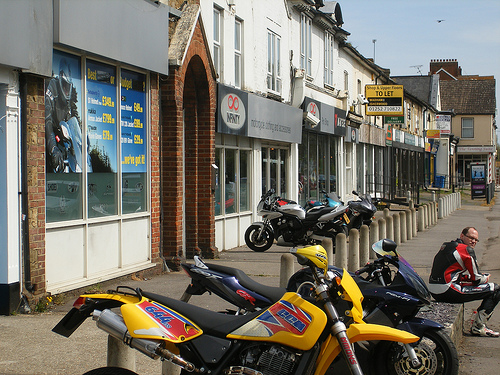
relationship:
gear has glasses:
[428, 227, 500, 338] [464, 233, 481, 244]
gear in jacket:
[428, 227, 500, 338] [426, 240, 489, 293]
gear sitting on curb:
[428, 227, 500, 338] [437, 303, 471, 357]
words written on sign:
[372, 87, 395, 102] [360, 85, 415, 123]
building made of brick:
[0, 0, 500, 316] [148, 0, 220, 261]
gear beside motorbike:
[428, 227, 500, 338] [183, 244, 463, 374]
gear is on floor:
[428, 227, 500, 338] [0, 187, 500, 375]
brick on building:
[170, 139, 183, 145] [2, 1, 305, 270]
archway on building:
[171, 50, 217, 261] [2, 1, 305, 270]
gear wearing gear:
[428, 227, 500, 338] [434, 235, 494, 315]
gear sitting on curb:
[428, 227, 500, 338] [408, 270, 480, 352]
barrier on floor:
[278, 254, 298, 293] [0, 187, 500, 375]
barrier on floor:
[334, 230, 349, 272] [0, 187, 500, 375]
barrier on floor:
[349, 225, 361, 269] [0, 187, 500, 375]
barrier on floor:
[368, 220, 381, 257] [0, 187, 500, 375]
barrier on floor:
[402, 207, 409, 241] [0, 187, 500, 375]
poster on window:
[44, 51, 150, 176] [39, 40, 153, 228]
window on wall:
[459, 116, 473, 138] [449, 112, 494, 152]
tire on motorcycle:
[385, 316, 459, 373] [176, 236, 457, 373]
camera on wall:
[348, 89, 368, 109] [338, 48, 385, 205]